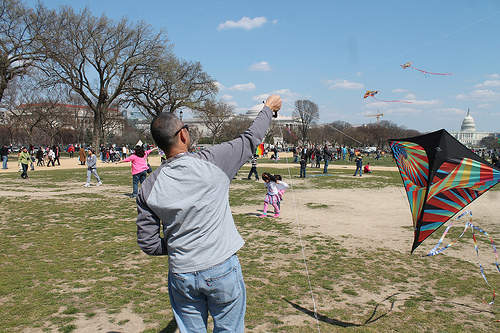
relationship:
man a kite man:
[130, 84, 472, 325] [122, 78, 295, 327]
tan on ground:
[228, 166, 498, 277] [2, 150, 497, 331]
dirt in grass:
[288, 174, 421, 247] [6, 153, 499, 325]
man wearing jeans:
[135, 94, 282, 333] [170, 251, 250, 330]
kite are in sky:
[363, 90, 415, 106] [7, 1, 494, 139]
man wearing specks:
[135, 94, 282, 333] [169, 122, 198, 140]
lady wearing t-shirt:
[116, 132, 152, 187] [120, 152, 154, 178]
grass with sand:
[3, 165, 497, 330] [250, 178, 497, 268]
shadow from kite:
[277, 288, 499, 331] [385, 117, 499, 259]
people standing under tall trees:
[80, 134, 134, 165] [0, 0, 237, 160]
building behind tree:
[451, 109, 491, 148] [472, 128, 499, 166]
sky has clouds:
[7, 1, 494, 139] [210, 9, 497, 136]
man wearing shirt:
[135, 94, 282, 333] [125, 105, 281, 279]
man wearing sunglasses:
[135, 94, 282, 333] [172, 120, 190, 132]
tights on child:
[261, 202, 281, 216] [259, 172, 290, 218]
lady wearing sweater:
[115, 145, 158, 199] [121, 149, 151, 176]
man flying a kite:
[135, 94, 282, 333] [388, 129, 495, 253]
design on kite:
[390, 138, 497, 248] [385, 117, 499, 259]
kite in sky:
[400, 58, 453, 79] [7, 1, 494, 139]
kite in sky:
[363, 88, 413, 106] [7, 1, 494, 139]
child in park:
[259, 172, 290, 218] [3, 130, 496, 329]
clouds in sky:
[195, 15, 500, 123] [7, 1, 494, 139]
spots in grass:
[5, 168, 489, 331] [0, 166, 500, 333]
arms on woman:
[118, 146, 159, 161] [110, 142, 155, 197]